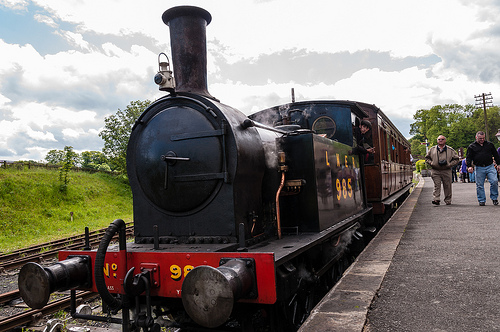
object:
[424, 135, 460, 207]
man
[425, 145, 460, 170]
jacket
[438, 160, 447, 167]
pockets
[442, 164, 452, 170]
hands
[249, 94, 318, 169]
smoke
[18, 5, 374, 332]
engine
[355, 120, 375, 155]
man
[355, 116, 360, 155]
window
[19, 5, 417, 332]
train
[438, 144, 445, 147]
neck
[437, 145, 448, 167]
camera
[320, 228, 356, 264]
smoke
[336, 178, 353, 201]
number 985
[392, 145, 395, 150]
light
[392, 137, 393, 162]
window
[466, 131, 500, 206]
man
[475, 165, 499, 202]
jeans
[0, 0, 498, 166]
sky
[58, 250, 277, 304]
fender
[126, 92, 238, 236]
front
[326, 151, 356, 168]
letters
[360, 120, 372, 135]
head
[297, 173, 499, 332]
sidewalk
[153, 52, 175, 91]
lantern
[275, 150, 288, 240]
steam pipe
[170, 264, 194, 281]
number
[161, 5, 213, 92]
smoke stack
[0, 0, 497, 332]
railway station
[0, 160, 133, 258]
grass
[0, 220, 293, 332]
track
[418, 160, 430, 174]
trees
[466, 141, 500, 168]
shirt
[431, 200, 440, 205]
shoes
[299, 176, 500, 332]
curb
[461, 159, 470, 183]
group of people